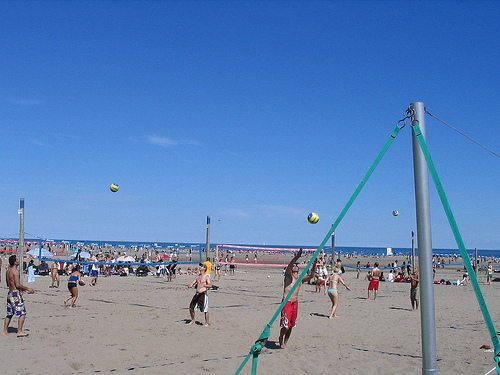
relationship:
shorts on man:
[188, 286, 210, 313] [183, 252, 221, 332]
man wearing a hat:
[184, 260, 214, 328] [198, 261, 206, 269]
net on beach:
[194, 229, 332, 284] [125, 272, 280, 335]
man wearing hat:
[184, 260, 216, 324] [200, 257, 212, 269]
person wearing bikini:
[62, 266, 87, 310] [64, 277, 81, 291]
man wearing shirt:
[201, 256, 214, 280] [202, 257, 214, 276]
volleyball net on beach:
[305, 210, 322, 224] [3, 242, 498, 372]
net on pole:
[28, 235, 217, 281] [400, 98, 441, 374]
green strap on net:
[209, 110, 424, 374] [31, 235, 200, 268]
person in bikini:
[323, 262, 352, 319] [322, 275, 342, 298]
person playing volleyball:
[59, 262, 84, 309] [306, 210, 321, 225]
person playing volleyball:
[280, 243, 306, 348] [306, 210, 321, 225]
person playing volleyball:
[323, 262, 352, 319] [306, 210, 321, 225]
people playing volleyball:
[364, 262, 382, 301] [306, 210, 321, 225]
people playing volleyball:
[1, 253, 36, 338] [306, 210, 321, 225]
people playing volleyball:
[406, 267, 418, 307] [106, 180, 118, 194]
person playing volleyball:
[323, 262, 352, 319] [393, 208, 400, 216]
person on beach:
[280, 243, 306, 348] [35, 312, 177, 365]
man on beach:
[184, 260, 214, 328] [35, 312, 177, 365]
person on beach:
[62, 266, 87, 310] [35, 312, 177, 365]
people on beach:
[5, 253, 35, 337] [35, 312, 177, 365]